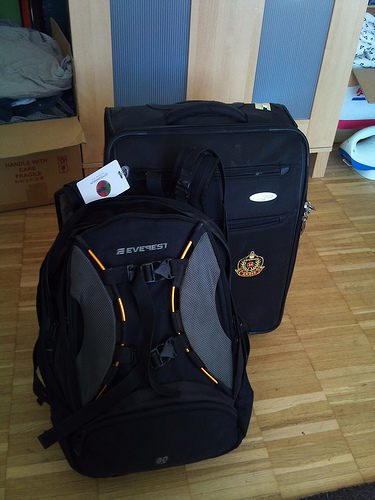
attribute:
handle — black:
[144, 94, 252, 126]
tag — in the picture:
[73, 155, 136, 206]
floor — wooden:
[290, 308, 369, 431]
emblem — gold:
[228, 244, 269, 282]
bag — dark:
[90, 98, 311, 341]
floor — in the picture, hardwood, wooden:
[8, 160, 373, 484]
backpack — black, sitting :
[34, 193, 255, 477]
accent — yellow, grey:
[85, 244, 128, 322]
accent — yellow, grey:
[160, 230, 221, 398]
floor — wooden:
[312, 185, 372, 491]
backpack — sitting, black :
[29, 147, 257, 478]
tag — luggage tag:
[75, 157, 132, 204]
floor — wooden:
[290, 280, 370, 387]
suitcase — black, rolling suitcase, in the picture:
[90, 99, 320, 334]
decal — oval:
[242, 187, 280, 203]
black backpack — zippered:
[19, 170, 274, 481]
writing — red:
[6, 149, 64, 194]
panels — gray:
[64, 221, 239, 404]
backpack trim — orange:
[53, 232, 236, 401]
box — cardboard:
[0, 114, 86, 214]